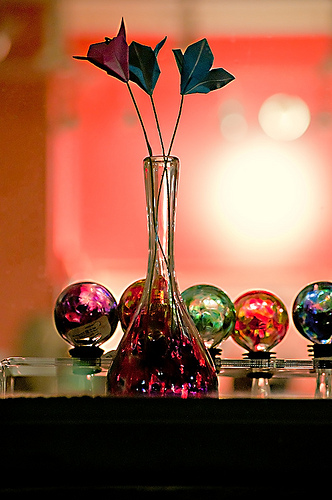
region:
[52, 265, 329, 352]
The smaller decorations to the bottom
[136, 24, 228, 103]
The blue flowers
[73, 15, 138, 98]
The pink flower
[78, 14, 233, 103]
There are three flowers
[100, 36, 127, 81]
A pink flower petal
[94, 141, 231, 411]
this is a vase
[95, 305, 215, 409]
pink bottom on base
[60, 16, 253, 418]
three flowers on a vase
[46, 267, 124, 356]
purple colored glass sphere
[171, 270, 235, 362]
green colored glass sphere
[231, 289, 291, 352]
red colored glass sphere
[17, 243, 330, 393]
glass spheres are bottle stoppers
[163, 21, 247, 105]
a teal blue flower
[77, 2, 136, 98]
a pink folded flower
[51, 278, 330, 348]
multi-colored lightbulbs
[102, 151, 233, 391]
clear glass bud vase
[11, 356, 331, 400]
reflective surface of a table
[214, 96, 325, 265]
blur of white lights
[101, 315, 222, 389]
red colored vase filler to support the flowers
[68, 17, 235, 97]
two green flowers and one red flower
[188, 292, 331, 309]
white lights reflected off bulbs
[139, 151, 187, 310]
narrow neck of a bud vase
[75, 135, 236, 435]
this is a vase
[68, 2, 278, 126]
3 folded fake flowers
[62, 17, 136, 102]
a pink folded flower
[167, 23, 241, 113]
teal blue folded flower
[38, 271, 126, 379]
a purple glass sphere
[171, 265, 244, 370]
a green glass sphere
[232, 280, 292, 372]
an orange glass sphere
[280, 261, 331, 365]
a blue glass sphere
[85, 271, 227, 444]
pink base on vase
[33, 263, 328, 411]
glass spheres are bottle stoppers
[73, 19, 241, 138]
flowers made of paper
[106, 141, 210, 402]
vase is made of glass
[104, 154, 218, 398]
multi-colored glass vase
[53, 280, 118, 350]
pink blown glass ball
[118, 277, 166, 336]
orange blown glass ball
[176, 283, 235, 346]
green blown glass ball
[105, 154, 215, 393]
a glass flower vase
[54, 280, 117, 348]
a colorful glass ball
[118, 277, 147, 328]
a colorful glass ball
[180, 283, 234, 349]
a colorful glass ball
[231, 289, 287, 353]
a colorful glass ball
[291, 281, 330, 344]
a colorful glass ball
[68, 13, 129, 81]
a red paper flower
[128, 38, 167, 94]
folded green paper leafs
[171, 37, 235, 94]
folded green paper leafs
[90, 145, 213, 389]
This is a glass vase.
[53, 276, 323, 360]
These are glass bulbs.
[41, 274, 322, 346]
These glass bulbs are very colorful.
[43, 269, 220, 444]
The bulbs and vase are sitting on a black table.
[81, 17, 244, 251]
There are 3 leaves in this vase.